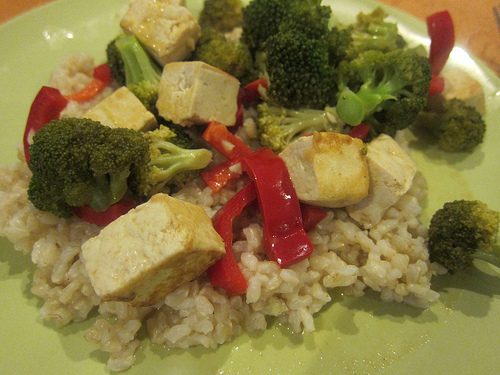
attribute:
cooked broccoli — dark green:
[28, 115, 150, 216]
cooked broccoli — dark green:
[138, 125, 212, 197]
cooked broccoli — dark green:
[428, 196, 498, 274]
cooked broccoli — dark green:
[411, 97, 485, 156]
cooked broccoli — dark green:
[336, 45, 433, 133]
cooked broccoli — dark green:
[331, 7, 407, 59]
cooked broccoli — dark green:
[264, 24, 345, 110]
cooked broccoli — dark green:
[255, 100, 344, 151]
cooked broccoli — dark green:
[240, 0, 335, 60]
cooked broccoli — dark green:
[104, 32, 165, 106]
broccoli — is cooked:
[334, 45, 436, 134]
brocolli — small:
[34, 102, 184, 204]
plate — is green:
[408, 288, 483, 352]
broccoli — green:
[34, 117, 206, 201]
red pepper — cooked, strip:
[235, 144, 315, 268]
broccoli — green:
[258, 28, 341, 110]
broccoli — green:
[238, 0, 333, 56]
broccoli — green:
[25, 114, 148, 218]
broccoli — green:
[428, 196, 499, 271]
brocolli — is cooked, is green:
[193, 0, 498, 168]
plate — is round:
[8, 4, 109, 56]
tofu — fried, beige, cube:
[68, 173, 264, 310]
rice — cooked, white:
[195, 295, 213, 315]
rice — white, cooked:
[300, 310, 315, 333]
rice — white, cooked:
[55, 281, 84, 303]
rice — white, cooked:
[109, 352, 135, 372]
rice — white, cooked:
[246, 277, 263, 304]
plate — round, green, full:
[14, 6, 499, 368]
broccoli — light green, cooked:
[331, 36, 432, 129]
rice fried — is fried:
[364, 187, 444, 304]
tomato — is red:
[196, 118, 316, 294]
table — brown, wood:
[1, 7, 484, 68]